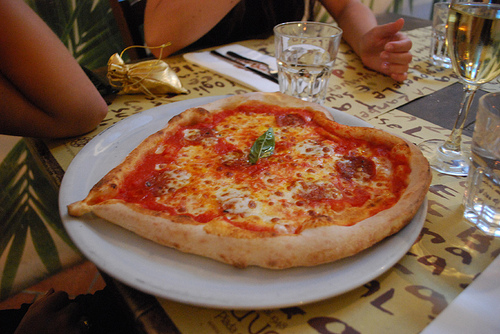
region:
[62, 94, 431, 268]
individual pizza on white plate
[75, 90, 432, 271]
deformed pizza on white plate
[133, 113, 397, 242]
melted cheese on pizza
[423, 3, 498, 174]
glass of wine on big table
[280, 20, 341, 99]
little cup of water on table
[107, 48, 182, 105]
little golden bag on table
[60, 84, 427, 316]
whtie plate where pizza is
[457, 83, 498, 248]
half cu of water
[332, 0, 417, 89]
left hand on table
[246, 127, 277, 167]
oregano leaf on pizza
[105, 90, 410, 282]
The pizza is on top of the plate.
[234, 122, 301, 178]
The leaf is on top of the pizza.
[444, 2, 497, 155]
The wine glass has white wine.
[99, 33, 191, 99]
The bag is gold colored.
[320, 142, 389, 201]
The pepperoni is on top of the cheese.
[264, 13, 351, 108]
The glass has water.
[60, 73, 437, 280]
The pizza is in the shape of a heart.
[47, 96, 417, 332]
The plate is on top of the table.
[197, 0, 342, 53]
The lady is wearing a black dress.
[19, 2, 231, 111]
The bag is between the two arms.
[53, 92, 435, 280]
heart shaped pizza on white plate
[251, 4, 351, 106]
clear water glass on table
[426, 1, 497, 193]
Wine glass on wood table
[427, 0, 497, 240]
glasses on a table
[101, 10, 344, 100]
Gold bag next to place setting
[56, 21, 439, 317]
Pizza on plate and water glass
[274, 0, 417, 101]
water glass and a woman's hand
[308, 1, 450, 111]
woman's hand resting on table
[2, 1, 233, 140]
Elbows on table next to gold bag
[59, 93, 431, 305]
pizza on a white plate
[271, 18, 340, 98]
a cup with liquid in it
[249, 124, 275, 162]
piece of basil on pizza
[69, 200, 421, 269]
crust of a pizza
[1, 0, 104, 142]
a person's bent arm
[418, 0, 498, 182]
a glass full of wine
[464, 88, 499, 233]
glass with water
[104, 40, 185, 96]
a small gold bag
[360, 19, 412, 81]
hand of a person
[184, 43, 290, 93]
utensils on a napkin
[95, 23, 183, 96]
small golden colored bown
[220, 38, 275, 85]
silver ware on top of table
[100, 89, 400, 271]
pizza on a plate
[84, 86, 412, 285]
heart shaped pizza on a plate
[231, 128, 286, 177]
one leaf on top of pizza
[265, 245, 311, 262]
white and brown crust of pizza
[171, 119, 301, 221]
white cheese on top of pizza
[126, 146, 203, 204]
red sauce on top of pizza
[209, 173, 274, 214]
orange burnt cheese on pizza